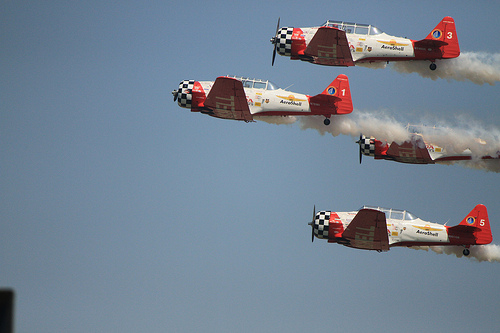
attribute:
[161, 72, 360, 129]
airplane — red, white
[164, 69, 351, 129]
airplane — red, white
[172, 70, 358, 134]
airplane — red, white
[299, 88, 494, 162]
clouds — white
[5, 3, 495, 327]
sky — blue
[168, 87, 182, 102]
propeller — red, white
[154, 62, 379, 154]
plane — checkered, black, white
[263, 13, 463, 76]
plane — four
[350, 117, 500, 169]
plane — numbered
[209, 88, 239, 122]
writing — white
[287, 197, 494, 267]
plane — white, red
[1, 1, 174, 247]
clouds — white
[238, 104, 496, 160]
smoke — white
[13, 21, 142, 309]
sky — clear, blue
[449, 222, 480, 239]
stabilizer — horizontal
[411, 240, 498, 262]
smoke — white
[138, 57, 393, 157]
plane — white, red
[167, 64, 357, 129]
plane — red, white, numbered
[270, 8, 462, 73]
plane — numbered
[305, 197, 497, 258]
plane — numbered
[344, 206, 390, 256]
wings — red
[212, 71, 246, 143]
wings — red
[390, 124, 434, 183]
wings — red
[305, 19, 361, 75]
wings — red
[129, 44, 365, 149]
airplane — white, red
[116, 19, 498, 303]
planes — checkered